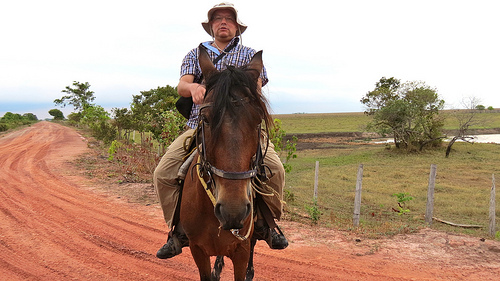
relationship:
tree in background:
[54, 80, 97, 125] [1, 0, 499, 162]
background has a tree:
[1, 0, 499, 162] [54, 80, 97, 125]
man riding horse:
[153, 2, 289, 259] [180, 46, 275, 280]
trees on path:
[0, 80, 326, 225] [0, 119, 499, 278]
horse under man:
[180, 46, 275, 280] [153, 2, 289, 259]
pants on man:
[154, 126, 284, 231] [153, 2, 289, 259]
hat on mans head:
[202, 2, 249, 37] [211, 9, 239, 42]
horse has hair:
[180, 46, 275, 280] [200, 63, 275, 157]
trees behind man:
[0, 80, 326, 225] [153, 2, 289, 259]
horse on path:
[180, 46, 275, 280] [0, 119, 499, 278]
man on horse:
[153, 2, 289, 259] [180, 46, 275, 280]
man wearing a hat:
[153, 2, 289, 259] [202, 2, 249, 37]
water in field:
[373, 130, 499, 146] [259, 107, 498, 239]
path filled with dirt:
[0, 119, 499, 278] [0, 119, 499, 280]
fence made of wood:
[109, 121, 499, 242] [312, 160, 498, 241]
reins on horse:
[190, 96, 272, 240] [180, 46, 275, 280]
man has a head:
[153, 2, 289, 259] [211, 9, 239, 42]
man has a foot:
[153, 2, 289, 259] [156, 233, 190, 260]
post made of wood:
[353, 165, 364, 227] [312, 160, 498, 241]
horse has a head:
[180, 46, 275, 280] [197, 42, 273, 231]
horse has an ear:
[180, 46, 275, 280] [197, 44, 218, 79]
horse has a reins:
[180, 46, 275, 280] [188, 96, 276, 241]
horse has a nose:
[180, 46, 275, 280] [212, 198, 253, 230]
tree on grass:
[360, 78, 444, 151] [262, 108, 499, 243]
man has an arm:
[153, 2, 289, 259] [178, 49, 209, 104]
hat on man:
[202, 2, 249, 37] [153, 2, 289, 259]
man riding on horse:
[153, 2, 289, 259] [180, 46, 275, 280]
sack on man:
[176, 36, 243, 120] [153, 2, 289, 259]